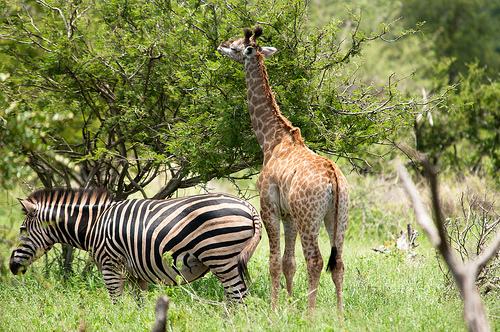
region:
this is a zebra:
[5, 185, 255, 301]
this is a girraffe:
[215, 20, 350, 315]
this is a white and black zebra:
[10, 180, 255, 310]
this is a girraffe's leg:
[293, 195, 321, 323]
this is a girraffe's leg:
[326, 192, 353, 330]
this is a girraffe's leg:
[257, 174, 285, 321]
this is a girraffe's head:
[214, 21, 278, 63]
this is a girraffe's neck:
[244, 61, 300, 148]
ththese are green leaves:
[29, 25, 215, 162]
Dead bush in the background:
[445, 196, 490, 288]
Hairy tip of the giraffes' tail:
[322, 240, 343, 279]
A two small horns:
[234, 20, 273, 43]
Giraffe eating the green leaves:
[198, 25, 288, 67]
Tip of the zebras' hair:
[30, 182, 120, 202]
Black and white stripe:
[188, 197, 253, 235]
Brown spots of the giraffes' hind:
[288, 173, 328, 215]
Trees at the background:
[386, 6, 485, 166]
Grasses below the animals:
[218, 283, 446, 330]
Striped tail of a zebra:
[233, 205, 268, 284]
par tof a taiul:
[246, 271, 269, 322]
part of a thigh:
[312, 222, 326, 244]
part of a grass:
[384, 279, 401, 307]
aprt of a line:
[228, 199, 250, 236]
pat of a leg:
[306, 254, 319, 293]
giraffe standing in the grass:
[215, 18, 362, 322]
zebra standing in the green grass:
[3, 173, 264, 312]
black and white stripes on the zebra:
[108, 217, 175, 243]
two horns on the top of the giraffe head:
[235, 23, 264, 48]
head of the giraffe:
[213, 25, 283, 73]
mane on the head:
[45, 186, 107, 209]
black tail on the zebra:
[233, 248, 258, 297]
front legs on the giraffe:
[265, 198, 296, 298]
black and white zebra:
[6, 177, 268, 310]